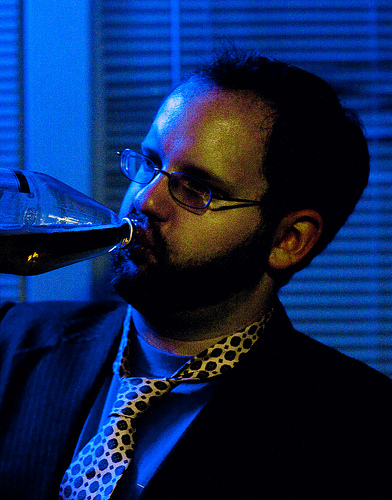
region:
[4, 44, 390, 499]
A man drinking.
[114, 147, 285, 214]
The man's glasses.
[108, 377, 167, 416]
The knot in the tie.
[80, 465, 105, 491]
Part of the tie.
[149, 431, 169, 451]
Part of the blue shirt.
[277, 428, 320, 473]
Part of the jacket.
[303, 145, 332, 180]
The man's dark hair.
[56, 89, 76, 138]
Part of the wall.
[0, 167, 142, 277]
A clear bottle with liquid inside.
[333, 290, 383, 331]
Part of the blinds.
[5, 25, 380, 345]
Man drinking from glass bottle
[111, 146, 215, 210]
eyeglasses with metal frames on man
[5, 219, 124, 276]
dark drink inside glass bottle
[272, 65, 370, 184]
dark hair on head of man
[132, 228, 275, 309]
scruffy beard on face of man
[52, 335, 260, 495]
man wearing tie over tshirt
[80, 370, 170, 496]
tie is yellow with black spots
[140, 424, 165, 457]
light blue t-shirt on man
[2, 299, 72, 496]
suit jacket with stripes on man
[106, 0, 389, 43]
window blinds in background of man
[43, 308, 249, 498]
man's tie is loosened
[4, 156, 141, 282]
tilted bottled beverage full of pale yellow liquid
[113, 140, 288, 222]
man is wearing a pair of glasses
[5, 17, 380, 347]
man having a drink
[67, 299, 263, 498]
man's tie is yellow with black circles and dots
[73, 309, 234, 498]
bright blue tee shirt under a sports jacket and tie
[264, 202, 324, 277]
exposed left ear of man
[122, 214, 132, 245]
small golden ring left behind from cap of bottle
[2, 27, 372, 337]
man is having a drink from a large bottle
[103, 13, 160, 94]
white venetian blind in blue lighting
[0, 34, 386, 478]
man is drinking soda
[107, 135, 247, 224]
the glasses on face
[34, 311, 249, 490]
yellow tie with black spots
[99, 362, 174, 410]
the knot of tie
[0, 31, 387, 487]
man wears a suit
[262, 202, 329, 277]
left ear of man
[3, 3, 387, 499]
man in front a window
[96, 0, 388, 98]
window covered with blinds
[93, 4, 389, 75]
blinds in front a window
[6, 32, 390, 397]
man drink directly from bottle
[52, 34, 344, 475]
face of the man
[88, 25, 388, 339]
face of the person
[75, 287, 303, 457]
color of the man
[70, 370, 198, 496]
a man wearing tie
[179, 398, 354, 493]
a man wearing suit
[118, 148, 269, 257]
a man wearing spects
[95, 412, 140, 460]
black marks in the tie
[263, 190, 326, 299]
ear of the person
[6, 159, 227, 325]
a man drinking wine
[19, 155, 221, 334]
a man holding bottle